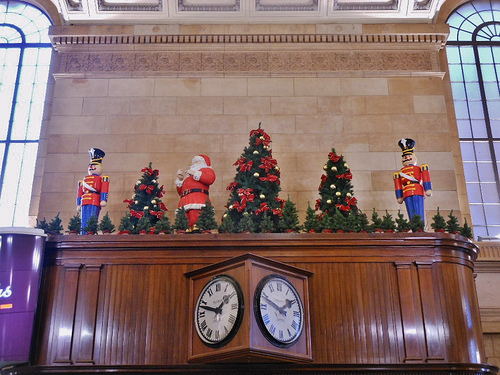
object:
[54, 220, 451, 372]
shelf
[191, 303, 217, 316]
hand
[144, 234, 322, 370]
cube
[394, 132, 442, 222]
decoration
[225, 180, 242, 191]
bow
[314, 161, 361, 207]
ornament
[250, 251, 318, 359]
clock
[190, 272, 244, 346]
face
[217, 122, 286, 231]
tree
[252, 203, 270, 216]
bows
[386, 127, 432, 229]
soldier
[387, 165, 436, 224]
uniform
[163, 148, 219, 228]
statue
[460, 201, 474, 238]
trees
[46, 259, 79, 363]
pillars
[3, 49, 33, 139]
sun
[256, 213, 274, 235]
trees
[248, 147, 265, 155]
balls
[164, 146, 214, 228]
santa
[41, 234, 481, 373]
mantle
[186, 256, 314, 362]
directions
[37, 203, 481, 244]
row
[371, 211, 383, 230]
trees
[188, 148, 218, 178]
head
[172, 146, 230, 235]
figurine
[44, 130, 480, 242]
display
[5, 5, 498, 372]
building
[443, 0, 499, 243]
window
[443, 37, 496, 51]
trim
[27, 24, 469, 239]
wall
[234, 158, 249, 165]
bows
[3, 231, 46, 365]
sign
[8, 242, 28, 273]
part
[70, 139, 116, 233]
mannequin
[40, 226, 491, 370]
platform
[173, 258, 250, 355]
views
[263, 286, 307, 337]
face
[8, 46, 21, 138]
pane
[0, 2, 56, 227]
window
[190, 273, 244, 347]
clock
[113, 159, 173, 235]
tree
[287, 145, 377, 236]
tree